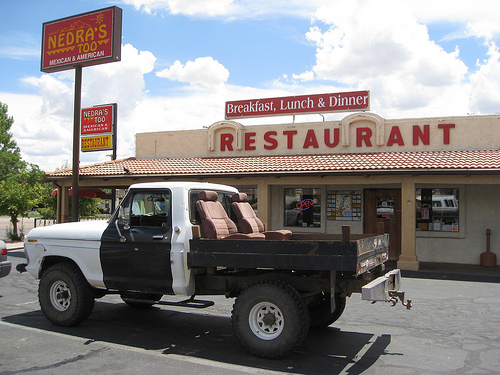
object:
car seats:
[231, 192, 292, 240]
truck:
[18, 181, 416, 357]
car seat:
[193, 189, 266, 242]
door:
[100, 188, 173, 292]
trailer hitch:
[388, 289, 413, 310]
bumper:
[361, 267, 413, 310]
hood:
[26, 219, 112, 240]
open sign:
[296, 198, 314, 210]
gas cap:
[34, 244, 45, 256]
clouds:
[301, 9, 470, 99]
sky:
[1, 0, 499, 172]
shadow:
[3, 298, 403, 374]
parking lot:
[1, 247, 499, 374]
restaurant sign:
[40, 4, 121, 73]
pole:
[69, 68, 81, 225]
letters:
[220, 133, 233, 151]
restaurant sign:
[74, 102, 116, 135]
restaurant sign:
[224, 90, 370, 119]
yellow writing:
[97, 23, 107, 39]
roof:
[40, 149, 500, 180]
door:
[360, 184, 404, 262]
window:
[283, 188, 321, 228]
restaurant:
[40, 113, 499, 280]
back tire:
[228, 278, 311, 358]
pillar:
[396, 181, 420, 271]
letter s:
[263, 130, 277, 149]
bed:
[191, 225, 390, 274]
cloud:
[155, 56, 231, 86]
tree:
[0, 99, 52, 237]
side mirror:
[114, 205, 131, 242]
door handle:
[153, 235, 164, 240]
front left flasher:
[28, 240, 37, 243]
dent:
[170, 254, 175, 269]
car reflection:
[415, 194, 460, 222]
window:
[415, 188, 459, 232]